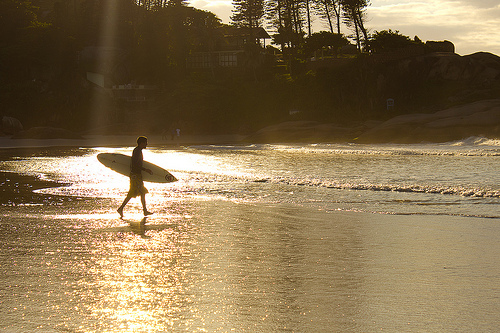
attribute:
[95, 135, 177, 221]
surfer — tall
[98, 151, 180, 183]
surfboard — white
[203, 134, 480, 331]
ocean — water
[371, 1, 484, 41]
sky — grey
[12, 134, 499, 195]
waves — beautiful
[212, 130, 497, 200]
waves — attractive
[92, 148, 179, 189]
surfboard — white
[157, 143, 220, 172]
sun — reflected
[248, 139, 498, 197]
waves — small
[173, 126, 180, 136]
shirt — white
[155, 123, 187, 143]
people — distant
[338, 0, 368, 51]
tree — tall